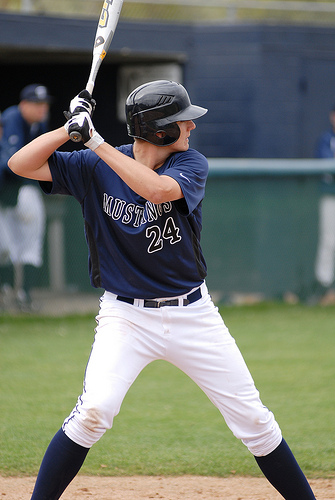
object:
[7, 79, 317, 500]
boy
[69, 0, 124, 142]
bat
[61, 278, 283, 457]
pants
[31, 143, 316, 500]
uniform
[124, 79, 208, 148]
helmet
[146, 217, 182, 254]
24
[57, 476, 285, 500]
ground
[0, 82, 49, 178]
man